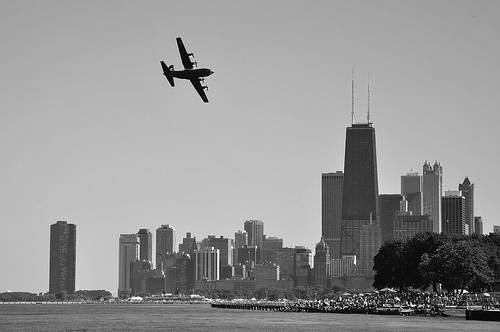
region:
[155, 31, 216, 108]
Plane flying in the air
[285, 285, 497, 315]
Crowd of people on shore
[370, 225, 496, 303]
Group of large trees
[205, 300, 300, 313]
Pier in the water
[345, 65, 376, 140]
Antennas on top of building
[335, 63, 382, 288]
Very tall building with antennas on top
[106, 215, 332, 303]
Series of tall buildings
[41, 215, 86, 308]
Individual building near water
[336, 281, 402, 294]
Umbrellas for the crowd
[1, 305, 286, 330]
Calm ocean water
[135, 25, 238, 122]
airplane with propellers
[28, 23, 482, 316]
airplane flying toward Chicago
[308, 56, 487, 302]
Tall Chicago buildings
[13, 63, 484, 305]
the Chicago skyline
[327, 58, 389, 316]
The Sears tower with two roof antennas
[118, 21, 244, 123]
plane with four propellers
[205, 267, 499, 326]
a crowd on a pier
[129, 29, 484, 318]
a crowd watching a plane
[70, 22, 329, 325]
a plane flying over water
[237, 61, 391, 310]
A building much taller than the surrounding buildings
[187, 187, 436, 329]
the buildings are visible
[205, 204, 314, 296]
the buildings are visible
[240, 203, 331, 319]
the buildings are visible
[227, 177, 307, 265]
the buildings are visible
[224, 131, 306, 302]
the buildings are visible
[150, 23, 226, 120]
the airplane in the air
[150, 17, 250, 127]
the airplane is flying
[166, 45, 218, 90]
the engine on plane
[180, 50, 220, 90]
the engine on the plane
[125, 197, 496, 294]
the buildings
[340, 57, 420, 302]
the tallest building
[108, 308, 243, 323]
the water is calm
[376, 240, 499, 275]
the trees with leaves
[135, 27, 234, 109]
Plane in the sky.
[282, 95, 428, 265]
Skyscrapers in the background.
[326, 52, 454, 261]
John Hancock tower in Chicago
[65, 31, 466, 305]
City with plane in the sky.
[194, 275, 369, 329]
People on the pier.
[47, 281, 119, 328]
Water in front of the buildings.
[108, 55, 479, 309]
Shorter building next to the tall building.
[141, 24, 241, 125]
Wings on the plane.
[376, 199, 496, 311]
Trees in front of the buildings.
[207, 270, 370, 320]
pier next to the water.